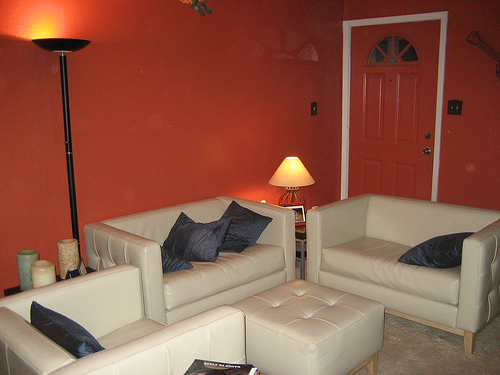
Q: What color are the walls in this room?
A: Red.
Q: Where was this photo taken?
A: Living room.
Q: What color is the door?
A: Red.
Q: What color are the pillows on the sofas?
A: Black.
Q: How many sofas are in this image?
A: Two.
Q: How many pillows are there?
A: Five.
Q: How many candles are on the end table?
A: Three.